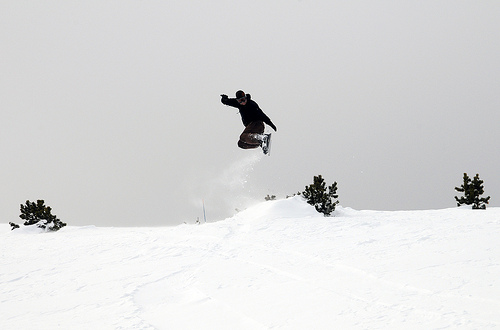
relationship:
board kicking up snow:
[266, 133, 272, 155] [180, 153, 264, 202]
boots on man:
[258, 135, 269, 153] [220, 89, 277, 149]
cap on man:
[236, 89, 246, 98] [220, 89, 277, 149]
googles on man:
[237, 95, 247, 103] [220, 89, 277, 149]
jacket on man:
[222, 93, 272, 125] [220, 89, 277, 149]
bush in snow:
[288, 174, 340, 219] [238, 193, 354, 220]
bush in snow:
[454, 173, 493, 209] [238, 193, 354, 220]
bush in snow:
[9, 199, 64, 234] [180, 153, 264, 202]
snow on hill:
[238, 193, 354, 220] [1, 209, 498, 329]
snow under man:
[180, 153, 264, 202] [220, 89, 277, 149]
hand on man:
[222, 93, 229, 101] [220, 89, 277, 149]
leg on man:
[241, 120, 266, 145] [220, 89, 277, 149]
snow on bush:
[20, 219, 56, 230] [9, 199, 64, 234]